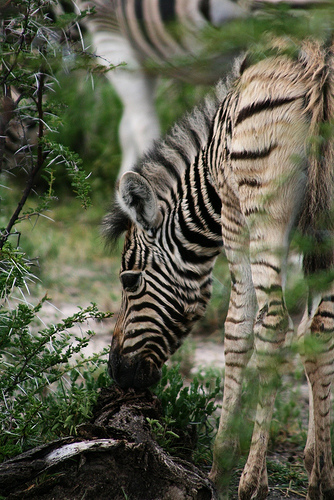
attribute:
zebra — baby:
[98, 49, 326, 488]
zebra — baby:
[100, 85, 277, 474]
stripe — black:
[248, 258, 282, 272]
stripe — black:
[240, 204, 272, 223]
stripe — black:
[226, 140, 278, 162]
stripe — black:
[233, 91, 301, 127]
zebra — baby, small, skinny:
[104, 24, 291, 481]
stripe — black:
[225, 360, 246, 368]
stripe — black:
[225, 331, 254, 343]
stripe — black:
[223, 315, 249, 323]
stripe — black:
[124, 309, 172, 344]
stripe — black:
[125, 327, 160, 337]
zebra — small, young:
[98, 33, 303, 493]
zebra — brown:
[96, 49, 323, 387]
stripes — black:
[142, 281, 179, 341]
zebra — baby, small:
[97, 43, 287, 487]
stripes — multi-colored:
[151, 267, 194, 319]